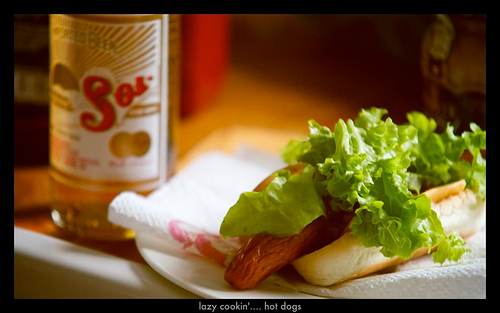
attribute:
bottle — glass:
[39, 12, 186, 251]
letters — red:
[73, 67, 154, 141]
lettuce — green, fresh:
[210, 99, 489, 274]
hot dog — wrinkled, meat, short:
[220, 207, 346, 290]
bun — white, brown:
[205, 141, 495, 298]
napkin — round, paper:
[84, 130, 489, 298]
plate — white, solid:
[127, 150, 482, 300]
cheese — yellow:
[425, 175, 469, 203]